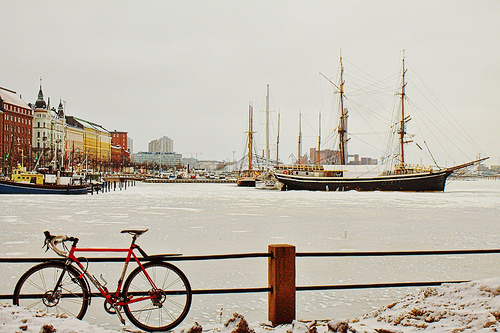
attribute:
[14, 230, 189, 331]
bike — red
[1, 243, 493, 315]
fence — black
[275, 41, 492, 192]
ship — long, black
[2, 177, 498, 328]
water — calm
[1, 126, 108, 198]
ship — docked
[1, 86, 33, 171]
building — red brick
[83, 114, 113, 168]
building — yellow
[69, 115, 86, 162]
building — brown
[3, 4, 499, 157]
sky — clear, hazy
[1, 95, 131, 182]
buildings — several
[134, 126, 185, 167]
building — distant